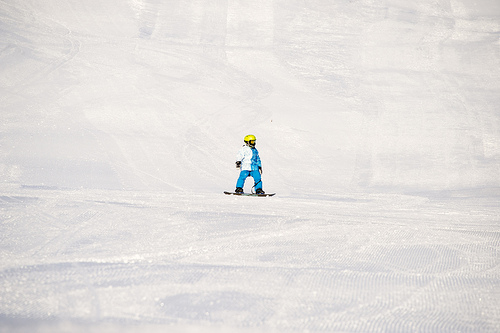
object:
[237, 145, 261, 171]
white jacket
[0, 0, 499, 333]
hill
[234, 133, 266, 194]
man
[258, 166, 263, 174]
hand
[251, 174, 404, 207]
white clouds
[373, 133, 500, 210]
snow boarder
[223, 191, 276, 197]
snowboard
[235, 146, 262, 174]
jacket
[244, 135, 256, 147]
helmet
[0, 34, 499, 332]
snow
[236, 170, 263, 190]
pants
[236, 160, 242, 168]
glove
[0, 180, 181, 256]
bottom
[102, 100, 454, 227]
background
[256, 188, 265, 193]
boots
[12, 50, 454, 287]
field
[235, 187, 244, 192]
shoes